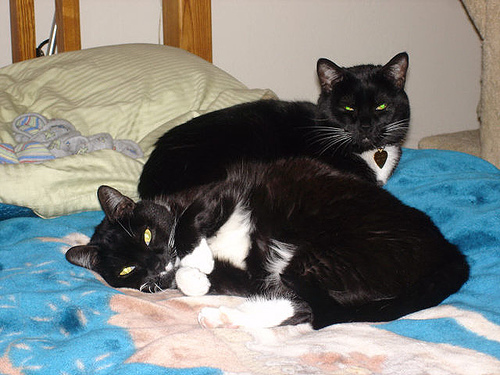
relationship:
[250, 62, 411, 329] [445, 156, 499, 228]
cats on bed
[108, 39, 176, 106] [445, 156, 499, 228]
pillow on bed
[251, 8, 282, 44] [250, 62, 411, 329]
wall behind cats